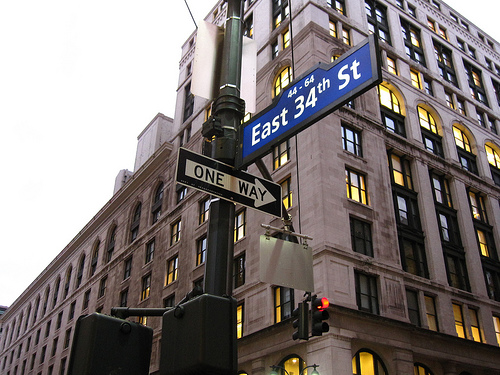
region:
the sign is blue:
[320, 81, 337, 99]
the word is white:
[257, 118, 284, 135]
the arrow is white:
[239, 175, 279, 209]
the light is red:
[317, 294, 330, 312]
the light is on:
[288, 354, 300, 366]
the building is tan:
[306, 154, 341, 221]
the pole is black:
[204, 237, 229, 273]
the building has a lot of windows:
[368, 141, 447, 254]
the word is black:
[195, 165, 224, 185]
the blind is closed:
[358, 279, 375, 306]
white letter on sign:
[251, 119, 261, 144]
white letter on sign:
[260, 120, 271, 139]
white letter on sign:
[271, 113, 281, 134]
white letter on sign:
[278, 105, 288, 128]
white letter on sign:
[315, 78, 323, 95]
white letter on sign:
[338, 61, 350, 89]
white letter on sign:
[348, 56, 360, 82]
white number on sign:
[293, 92, 304, 117]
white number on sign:
[305, 84, 318, 109]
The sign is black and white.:
[173, 139, 291, 224]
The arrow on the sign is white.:
[168, 138, 297, 233]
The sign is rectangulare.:
[171, 143, 301, 227]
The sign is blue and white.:
[238, 28, 390, 168]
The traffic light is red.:
[308, 284, 335, 341]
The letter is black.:
[201, 158, 217, 190]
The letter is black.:
[213, 166, 229, 191]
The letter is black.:
[235, 176, 249, 199]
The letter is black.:
[248, 180, 259, 205]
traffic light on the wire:
[313, 295, 330, 334]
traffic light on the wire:
[291, 303, 308, 338]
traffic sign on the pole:
[171, 140, 296, 215]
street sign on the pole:
[240, 29, 386, 156]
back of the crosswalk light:
[60, 307, 152, 372]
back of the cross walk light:
[160, 293, 240, 373]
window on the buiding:
[337, 113, 371, 157]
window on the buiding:
[349, 266, 381, 316]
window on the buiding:
[389, 182, 421, 229]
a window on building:
[339, 166, 371, 205]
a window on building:
[339, 115, 377, 158]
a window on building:
[382, 138, 424, 197]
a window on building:
[398, 192, 428, 229]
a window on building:
[349, 216, 379, 251]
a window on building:
[351, 271, 387, 318]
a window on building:
[400, 287, 434, 329]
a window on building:
[449, 299, 481, 339]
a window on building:
[442, 213, 467, 243]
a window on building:
[429, 167, 465, 205]